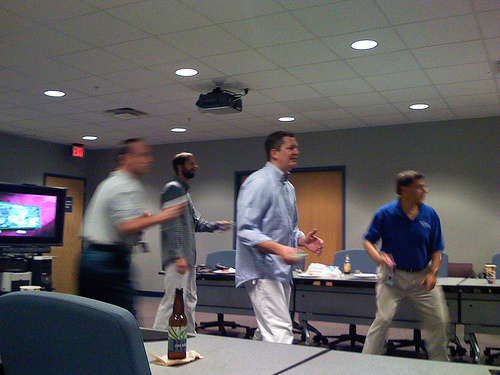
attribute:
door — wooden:
[229, 161, 350, 271]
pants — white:
[364, 259, 454, 356]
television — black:
[0, 181, 67, 249]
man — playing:
[73, 135, 187, 310]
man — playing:
[152, 150, 232, 332]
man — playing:
[232, 128, 324, 343]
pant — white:
[246, 262, 363, 359]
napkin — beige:
[145, 345, 205, 367]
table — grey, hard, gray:
[138, 328, 495, 373]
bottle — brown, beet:
[170, 285, 189, 360]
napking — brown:
[145, 348, 202, 365]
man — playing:
[360, 167, 454, 366]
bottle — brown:
[162, 284, 199, 361]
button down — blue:
[233, 164, 305, 289]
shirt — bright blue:
[361, 198, 447, 275]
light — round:
[344, 30, 377, 56]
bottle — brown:
[165, 283, 188, 362]